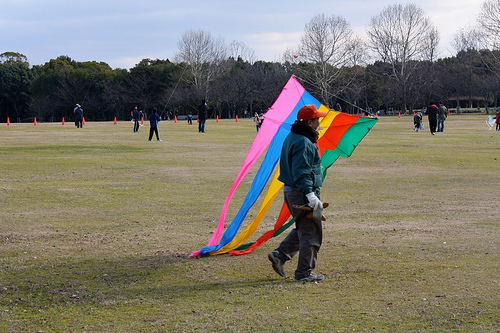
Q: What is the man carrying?
A: A kite.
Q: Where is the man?
A: In a field.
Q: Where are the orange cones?
A: In the field.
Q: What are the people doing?
A: Flying kites.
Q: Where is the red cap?
A: On the man's head.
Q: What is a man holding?
A: A kite.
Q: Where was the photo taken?
A: At a park.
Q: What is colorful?
A: The kite.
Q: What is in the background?
A: Trees.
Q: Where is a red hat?
A: On man's head.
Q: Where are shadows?
A: On the grass.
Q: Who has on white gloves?
A: Man holding kite.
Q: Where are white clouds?
A: In the sky.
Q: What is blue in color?
A: The sky.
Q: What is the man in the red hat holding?
A: Kite.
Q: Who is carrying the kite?
A: The man in the red hat.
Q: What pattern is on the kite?
A: Stripes.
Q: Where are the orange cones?
A: On the ground.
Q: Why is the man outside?
A: To fly a kite.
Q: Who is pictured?
A: A man with a kite.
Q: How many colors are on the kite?
A: 5.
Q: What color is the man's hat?
A: Red.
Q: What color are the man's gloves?
A: White.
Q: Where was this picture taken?
A: A park.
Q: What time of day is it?
A: Daytime.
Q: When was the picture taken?
A: Daylight.